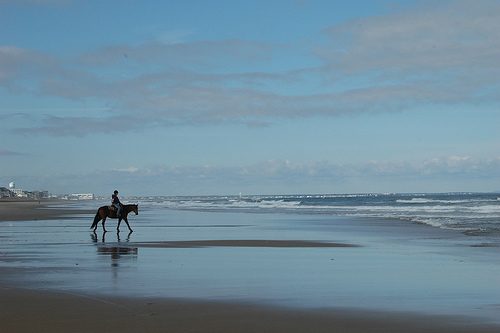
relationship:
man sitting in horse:
[109, 187, 124, 215] [85, 201, 140, 248]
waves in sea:
[250, 197, 313, 208] [190, 188, 349, 223]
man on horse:
[109, 190, 124, 218] [81, 197, 144, 246]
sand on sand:
[0, 198, 499, 332] [0, 198, 499, 332]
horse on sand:
[90, 203, 139, 232] [0, 198, 498, 330]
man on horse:
[109, 190, 124, 218] [88, 204, 137, 232]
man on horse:
[109, 190, 124, 218] [94, 202, 138, 237]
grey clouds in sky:
[19, 58, 489, 135] [166, 55, 332, 164]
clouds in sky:
[258, 42, 466, 118] [6, 6, 496, 200]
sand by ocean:
[0, 198, 499, 332] [202, 176, 487, 236]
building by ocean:
[51, 158, 107, 218] [175, 169, 487, 326]